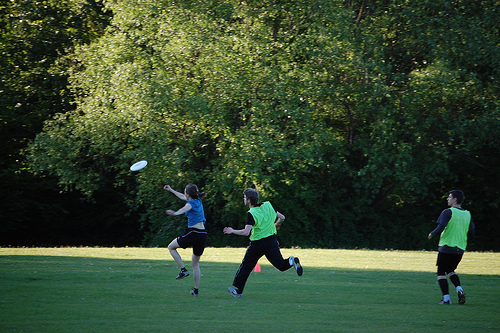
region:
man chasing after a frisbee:
[225, 169, 313, 296]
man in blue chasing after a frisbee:
[155, 158, 210, 298]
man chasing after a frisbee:
[418, 153, 488, 304]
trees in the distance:
[233, 49, 407, 150]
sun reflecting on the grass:
[306, 247, 420, 279]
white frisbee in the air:
[120, 160, 157, 173]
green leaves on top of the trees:
[133, 28, 183, 53]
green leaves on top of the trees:
[278, 63, 326, 105]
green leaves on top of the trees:
[407, 102, 452, 150]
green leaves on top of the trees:
[22, 13, 58, 75]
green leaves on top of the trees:
[389, 127, 416, 169]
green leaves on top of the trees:
[66, 5, 98, 31]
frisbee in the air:
[131, 151, 153, 184]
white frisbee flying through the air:
[126, 156, 148, 173]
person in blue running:
[163, 179, 205, 291]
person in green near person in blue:
[163, 178, 303, 296]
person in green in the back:
[429, 193, 472, 308]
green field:
[3, 248, 498, 331]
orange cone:
[251, 259, 261, 270]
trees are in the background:
[0, 3, 497, 248]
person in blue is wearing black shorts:
[162, 182, 205, 294]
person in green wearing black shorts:
[426, 191, 471, 306]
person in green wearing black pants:
[222, 186, 302, 298]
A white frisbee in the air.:
[109, 154, 152, 182]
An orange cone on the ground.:
[247, 249, 267, 276]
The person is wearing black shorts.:
[158, 228, 218, 260]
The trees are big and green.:
[101, 50, 425, 203]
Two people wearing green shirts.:
[242, 206, 499, 262]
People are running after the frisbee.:
[150, 173, 480, 299]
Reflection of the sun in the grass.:
[284, 234, 415, 281]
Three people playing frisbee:
[162, 181, 473, 307]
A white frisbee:
[131, 159, 148, 171]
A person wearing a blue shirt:
[184, 199, 204, 224]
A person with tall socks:
[438, 272, 461, 293]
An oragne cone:
[254, 262, 261, 274]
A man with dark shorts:
[177, 225, 205, 253]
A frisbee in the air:
[129, 158, 147, 173]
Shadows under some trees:
[2, 172, 147, 247]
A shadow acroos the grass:
[1, 255, 498, 331]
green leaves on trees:
[3, 1, 498, 245]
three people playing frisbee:
[129, 159, 469, 301]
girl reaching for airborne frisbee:
[130, 159, 207, 295]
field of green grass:
[0, 248, 498, 331]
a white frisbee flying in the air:
[114, 145, 159, 187]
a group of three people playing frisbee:
[97, 133, 495, 320]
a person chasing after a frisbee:
[116, 142, 215, 301]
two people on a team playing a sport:
[222, 151, 482, 319]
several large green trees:
[9, 3, 481, 234]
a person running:
[210, 165, 322, 312]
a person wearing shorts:
[147, 177, 222, 310]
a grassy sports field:
[2, 238, 492, 319]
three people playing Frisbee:
[122, 158, 475, 309]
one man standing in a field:
[424, 187, 475, 308]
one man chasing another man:
[162, 178, 308, 300]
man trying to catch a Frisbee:
[127, 155, 209, 298]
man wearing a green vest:
[422, 190, 476, 306]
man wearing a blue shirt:
[160, 180, 210, 300]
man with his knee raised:
[160, 180, 211, 299]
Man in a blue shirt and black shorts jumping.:
[165, 182, 206, 297]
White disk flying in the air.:
[125, 156, 146, 172]